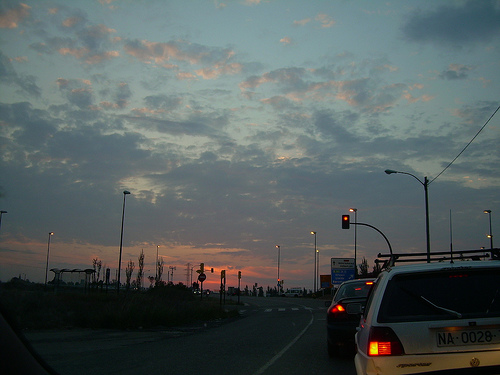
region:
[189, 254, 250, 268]
pink sky at sunset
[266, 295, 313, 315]
white lines on the street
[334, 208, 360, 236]
traffic light signaling on red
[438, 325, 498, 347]
black and white license plate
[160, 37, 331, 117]
thick clouds in the sky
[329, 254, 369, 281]
blue and white traffic sign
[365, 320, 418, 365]
red brake light on a car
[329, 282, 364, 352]
a black car driving on the street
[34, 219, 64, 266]
street light shining overhead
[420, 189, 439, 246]
a pole supporting a street light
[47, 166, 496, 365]
A city street at night.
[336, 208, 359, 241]
The streetlight is on red.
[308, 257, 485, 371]
Breaklights are on.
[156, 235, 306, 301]
The sunset is red.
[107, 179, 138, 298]
The streetlight is tall.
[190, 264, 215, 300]
The stoplight is red.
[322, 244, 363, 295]
The street sign is blue.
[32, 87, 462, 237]
The clouds in the sky.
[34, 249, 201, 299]
The trees are dark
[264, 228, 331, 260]
The streetlights are on.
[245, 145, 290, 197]
part of a cloud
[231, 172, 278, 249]
part of a cloud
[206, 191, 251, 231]
part of a cloud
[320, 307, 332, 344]
edge of a car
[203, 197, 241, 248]
part of a cloud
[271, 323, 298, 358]
part of a line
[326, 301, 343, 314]
a car's tail light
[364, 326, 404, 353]
a car's tail light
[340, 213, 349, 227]
a stop light reading red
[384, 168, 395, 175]
housing for a streetlight bulb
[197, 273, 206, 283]
a sign in the distance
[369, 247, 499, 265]
roof rack on a car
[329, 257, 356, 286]
a blue and white sign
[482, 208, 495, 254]
light posts in the distance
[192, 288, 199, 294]
a car in the distance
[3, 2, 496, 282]
cloud cover in sky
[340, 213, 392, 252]
glowing traffic light on curved pole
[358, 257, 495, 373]
back of white car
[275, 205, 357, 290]
glowing street lights on poles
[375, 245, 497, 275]
rack on top of roof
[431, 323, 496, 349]
license plate on car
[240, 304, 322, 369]
lines of paved road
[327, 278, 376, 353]
glowing brake light on car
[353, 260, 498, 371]
a stopped white car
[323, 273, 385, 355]
a stopped car on street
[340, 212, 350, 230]
an electric traffic signal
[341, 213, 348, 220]
a red stop traffic signal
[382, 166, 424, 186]
an overhead street light